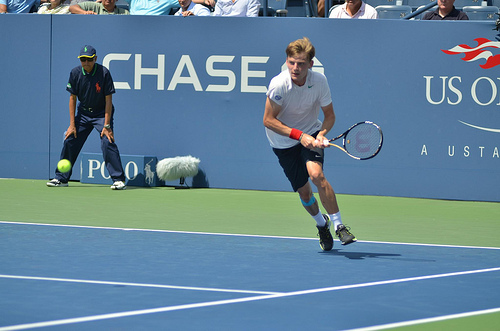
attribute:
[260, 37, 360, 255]
man — running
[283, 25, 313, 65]
hair — short, blond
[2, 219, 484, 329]
tennis court — white, blue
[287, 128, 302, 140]
sweatband — red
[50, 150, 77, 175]
ball — green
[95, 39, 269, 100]
letters — white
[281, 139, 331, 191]
shorts — black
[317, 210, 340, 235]
socks — white